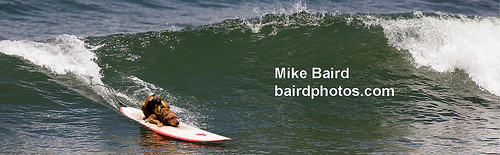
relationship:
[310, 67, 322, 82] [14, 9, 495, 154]
letter on water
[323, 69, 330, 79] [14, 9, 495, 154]
letter on water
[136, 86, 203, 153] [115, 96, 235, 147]
canine on surf board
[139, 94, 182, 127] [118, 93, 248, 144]
canine on surfboard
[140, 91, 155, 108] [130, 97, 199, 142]
clothing on dog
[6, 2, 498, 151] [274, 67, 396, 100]
image has credit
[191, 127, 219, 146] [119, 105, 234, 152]
logo on board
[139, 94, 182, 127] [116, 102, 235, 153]
canine on surf board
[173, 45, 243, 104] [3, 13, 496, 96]
water has wave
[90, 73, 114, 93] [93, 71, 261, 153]
cord on surf board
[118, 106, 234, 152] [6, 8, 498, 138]
board on wave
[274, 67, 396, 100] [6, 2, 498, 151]
credit on image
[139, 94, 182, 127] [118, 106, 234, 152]
canine on board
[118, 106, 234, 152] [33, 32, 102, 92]
board forms wake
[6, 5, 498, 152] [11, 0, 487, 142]
choppines on water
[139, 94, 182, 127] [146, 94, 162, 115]
canine has clothing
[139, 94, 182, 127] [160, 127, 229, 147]
canine on board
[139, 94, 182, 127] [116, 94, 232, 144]
canine sitting on board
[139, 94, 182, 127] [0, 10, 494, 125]
canine riding wave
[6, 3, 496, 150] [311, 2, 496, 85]
ocean has waves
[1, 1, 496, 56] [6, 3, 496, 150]
tide on ocean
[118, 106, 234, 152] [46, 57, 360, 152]
board on water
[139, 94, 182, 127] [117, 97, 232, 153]
canine laying on board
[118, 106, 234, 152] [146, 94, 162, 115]
board has clothing